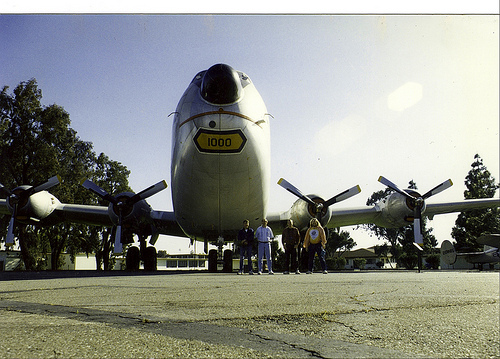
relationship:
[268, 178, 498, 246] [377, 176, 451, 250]
wing has propeller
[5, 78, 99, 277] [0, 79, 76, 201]
tree has leaves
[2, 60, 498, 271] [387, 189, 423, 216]
plane has engine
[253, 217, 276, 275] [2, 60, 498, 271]
man near plane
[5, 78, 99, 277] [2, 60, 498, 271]
tree near plane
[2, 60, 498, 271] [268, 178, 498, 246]
plane has wing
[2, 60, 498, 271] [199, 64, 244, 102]
plane has nose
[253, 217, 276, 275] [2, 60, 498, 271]
man standing in front of plane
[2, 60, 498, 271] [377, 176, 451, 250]
plane has propeller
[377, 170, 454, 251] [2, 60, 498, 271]
propeller on plane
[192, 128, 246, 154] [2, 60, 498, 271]
marker on plane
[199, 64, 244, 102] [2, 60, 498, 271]
nose on plane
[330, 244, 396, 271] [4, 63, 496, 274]
house behind airplane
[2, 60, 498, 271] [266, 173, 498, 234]
plane has wing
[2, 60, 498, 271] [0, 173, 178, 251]
plane has wing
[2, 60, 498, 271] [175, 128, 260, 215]
plane has fuselage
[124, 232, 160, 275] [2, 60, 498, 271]
landing gear on plane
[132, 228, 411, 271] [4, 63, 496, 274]
buildings behind airplane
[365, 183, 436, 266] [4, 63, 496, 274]
tree behind airplane